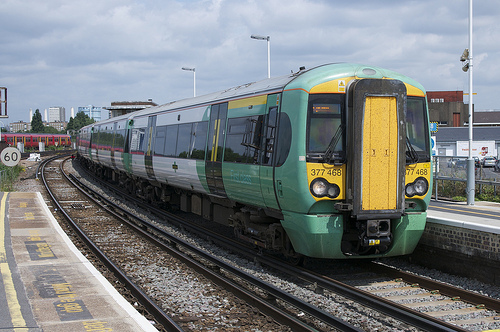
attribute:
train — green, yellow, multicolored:
[76, 61, 436, 262]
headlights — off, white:
[310, 174, 429, 199]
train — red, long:
[1, 129, 72, 151]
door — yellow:
[360, 94, 402, 213]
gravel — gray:
[353, 269, 492, 329]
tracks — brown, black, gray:
[60, 149, 498, 329]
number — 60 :
[1, 149, 20, 164]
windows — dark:
[76, 114, 266, 166]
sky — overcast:
[3, 1, 499, 126]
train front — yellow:
[300, 62, 435, 263]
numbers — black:
[308, 166, 342, 179]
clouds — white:
[1, 5, 499, 124]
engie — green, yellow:
[196, 63, 434, 262]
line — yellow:
[2, 186, 28, 331]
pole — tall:
[466, 0, 475, 203]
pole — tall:
[266, 33, 271, 87]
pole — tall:
[192, 65, 198, 99]